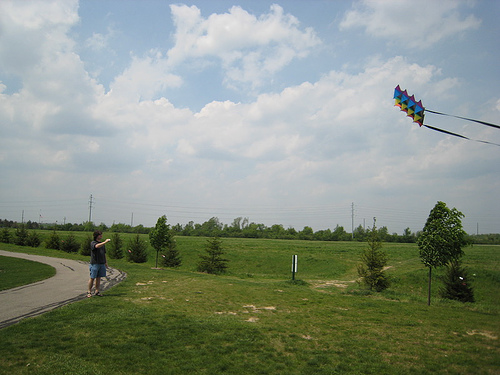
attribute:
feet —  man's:
[77, 286, 115, 306]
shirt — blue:
[87, 240, 109, 267]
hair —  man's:
[95, 227, 107, 240]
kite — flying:
[388, 79, 429, 129]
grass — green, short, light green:
[8, 220, 490, 372]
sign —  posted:
[266, 255, 304, 282]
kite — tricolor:
[386, 78, 428, 134]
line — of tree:
[5, 215, 497, 244]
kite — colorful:
[363, 66, 437, 139]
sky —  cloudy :
[116, 51, 246, 168]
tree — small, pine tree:
[196, 229, 229, 276]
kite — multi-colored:
[386, 79, 498, 146]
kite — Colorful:
[392, 85, 497, 132]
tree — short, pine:
[193, 230, 230, 276]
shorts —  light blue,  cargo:
[85, 263, 107, 281]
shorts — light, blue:
[90, 263, 109, 278]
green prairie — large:
[32, 223, 488, 341]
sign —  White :
[284, 247, 307, 282]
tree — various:
[417, 199, 470, 294]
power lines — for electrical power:
[0, 185, 498, 240]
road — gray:
[1, 242, 97, 328]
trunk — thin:
[422, 255, 438, 313]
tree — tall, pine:
[414, 200, 469, 307]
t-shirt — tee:
[92, 238, 108, 264]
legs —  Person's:
[87, 261, 107, 294]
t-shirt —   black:
[90, 238, 104, 263]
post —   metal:
[292, 251, 296, 283]